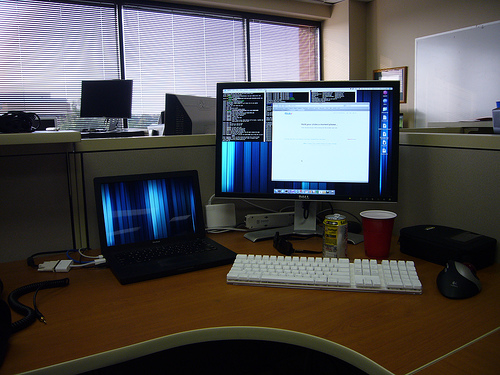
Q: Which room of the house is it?
A: It is an office.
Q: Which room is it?
A: It is an office.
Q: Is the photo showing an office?
A: Yes, it is showing an office.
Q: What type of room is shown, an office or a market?
A: It is an office.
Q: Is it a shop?
A: No, it is an office.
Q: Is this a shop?
A: No, it is an office.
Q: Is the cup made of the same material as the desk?
A: No, the cup is made of plastic and the desk is made of wood.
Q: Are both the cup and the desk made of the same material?
A: No, the cup is made of plastic and the desk is made of wood.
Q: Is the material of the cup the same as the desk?
A: No, the cup is made of plastic and the desk is made of wood.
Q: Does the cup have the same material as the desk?
A: No, the cup is made of plastic and the desk is made of wood.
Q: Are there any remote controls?
A: No, there are no remote controls.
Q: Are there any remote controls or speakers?
A: No, there are no remote controls or speakers.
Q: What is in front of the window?
A: The screen is in front of the window.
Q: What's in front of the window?
A: The screen is in front of the window.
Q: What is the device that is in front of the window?
A: The device is a screen.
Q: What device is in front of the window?
A: The device is a screen.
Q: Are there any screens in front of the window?
A: Yes, there is a screen in front of the window.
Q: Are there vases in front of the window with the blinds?
A: No, there is a screen in front of the window.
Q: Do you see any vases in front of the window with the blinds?
A: No, there is a screen in front of the window.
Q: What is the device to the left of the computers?
A: The device is a screen.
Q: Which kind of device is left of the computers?
A: The device is a screen.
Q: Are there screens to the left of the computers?
A: Yes, there is a screen to the left of the computers.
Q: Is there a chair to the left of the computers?
A: No, there is a screen to the left of the computers.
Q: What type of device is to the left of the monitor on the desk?
A: The device is a screen.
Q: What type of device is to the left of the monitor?
A: The device is a screen.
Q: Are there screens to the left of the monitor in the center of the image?
A: Yes, there is a screen to the left of the monitor.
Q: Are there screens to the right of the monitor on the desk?
A: No, the screen is to the left of the monitor.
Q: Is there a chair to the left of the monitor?
A: No, there is a screen to the left of the monitor.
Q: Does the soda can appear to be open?
A: Yes, the soda can is open.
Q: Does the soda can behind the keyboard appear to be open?
A: Yes, the soda can is open.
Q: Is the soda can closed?
A: No, the soda can is open.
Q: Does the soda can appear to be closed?
A: No, the soda can is open.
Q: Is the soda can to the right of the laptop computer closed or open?
A: The soda can is open.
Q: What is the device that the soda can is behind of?
A: The device is a keyboard.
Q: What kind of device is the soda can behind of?
A: The soda can is behind the keyboard.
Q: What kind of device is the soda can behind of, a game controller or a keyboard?
A: The soda can is behind a keyboard.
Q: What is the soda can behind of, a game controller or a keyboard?
A: The soda can is behind a keyboard.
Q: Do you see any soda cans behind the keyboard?
A: Yes, there is a soda can behind the keyboard.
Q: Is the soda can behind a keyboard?
A: Yes, the soda can is behind a keyboard.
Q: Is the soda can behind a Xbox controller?
A: No, the soda can is behind a keyboard.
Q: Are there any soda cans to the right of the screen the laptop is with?
A: Yes, there is a soda can to the right of the screen.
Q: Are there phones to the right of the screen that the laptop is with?
A: No, there is a soda can to the right of the screen.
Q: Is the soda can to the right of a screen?
A: Yes, the soda can is to the right of a screen.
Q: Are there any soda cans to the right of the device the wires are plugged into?
A: Yes, there is a soda can to the right of the laptop computer.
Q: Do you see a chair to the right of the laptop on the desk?
A: No, there is a soda can to the right of the laptop.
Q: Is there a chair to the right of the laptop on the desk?
A: No, there is a soda can to the right of the laptop.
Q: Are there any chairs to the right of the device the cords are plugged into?
A: No, there is a soda can to the right of the laptop.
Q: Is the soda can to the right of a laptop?
A: Yes, the soda can is to the right of a laptop.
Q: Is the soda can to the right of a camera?
A: No, the soda can is to the right of a laptop.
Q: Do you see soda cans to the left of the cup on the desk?
A: Yes, there is a soda can to the left of the cup.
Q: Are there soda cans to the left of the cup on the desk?
A: Yes, there is a soda can to the left of the cup.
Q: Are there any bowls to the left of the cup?
A: No, there is a soda can to the left of the cup.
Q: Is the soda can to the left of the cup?
A: Yes, the soda can is to the left of the cup.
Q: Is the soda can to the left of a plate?
A: No, the soda can is to the left of the cup.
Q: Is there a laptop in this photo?
A: Yes, there is a laptop.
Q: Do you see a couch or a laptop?
A: Yes, there is a laptop.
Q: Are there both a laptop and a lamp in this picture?
A: No, there is a laptop but no lamps.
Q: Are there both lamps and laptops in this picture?
A: No, there is a laptop but no lamps.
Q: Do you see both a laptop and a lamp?
A: No, there is a laptop but no lamps.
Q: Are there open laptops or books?
A: Yes, there is an open laptop.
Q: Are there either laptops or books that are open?
A: Yes, the laptop is open.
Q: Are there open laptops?
A: Yes, there is an open laptop.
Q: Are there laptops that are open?
A: Yes, there is an open laptop.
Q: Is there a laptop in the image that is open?
A: Yes, there is a laptop that is open.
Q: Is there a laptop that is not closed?
A: Yes, there is a open laptop.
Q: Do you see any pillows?
A: No, there are no pillows.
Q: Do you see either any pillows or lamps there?
A: No, there are no pillows or lamps.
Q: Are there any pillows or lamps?
A: No, there are no pillows or lamps.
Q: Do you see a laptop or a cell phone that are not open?
A: No, there is a laptop but it is open.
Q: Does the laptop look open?
A: Yes, the laptop is open.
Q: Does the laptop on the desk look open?
A: Yes, the laptop is open.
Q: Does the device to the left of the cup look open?
A: Yes, the laptop is open.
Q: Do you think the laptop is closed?
A: No, the laptop is open.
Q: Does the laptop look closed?
A: No, the laptop is open.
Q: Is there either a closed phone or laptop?
A: No, there is a laptop but it is open.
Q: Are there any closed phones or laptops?
A: No, there is a laptop but it is open.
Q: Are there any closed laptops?
A: No, there is a laptop but it is open.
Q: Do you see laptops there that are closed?
A: No, there is a laptop but it is open.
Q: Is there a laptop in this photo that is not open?
A: No, there is a laptop but it is open.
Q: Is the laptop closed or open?
A: The laptop is open.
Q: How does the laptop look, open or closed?
A: The laptop is open.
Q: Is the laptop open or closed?
A: The laptop is open.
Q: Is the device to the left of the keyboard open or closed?
A: The laptop is open.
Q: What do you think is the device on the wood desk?
A: The device is a laptop.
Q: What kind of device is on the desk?
A: The device is a laptop.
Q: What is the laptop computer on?
A: The laptop computer is on the desk.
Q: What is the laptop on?
A: The laptop computer is on the desk.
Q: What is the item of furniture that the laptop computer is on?
A: The piece of furniture is a desk.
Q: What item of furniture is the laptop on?
A: The laptop computer is on the desk.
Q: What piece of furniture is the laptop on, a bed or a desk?
A: The laptop is on a desk.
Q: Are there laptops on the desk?
A: Yes, there is a laptop on the desk.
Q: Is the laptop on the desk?
A: Yes, the laptop is on the desk.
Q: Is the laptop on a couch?
A: No, the laptop is on the desk.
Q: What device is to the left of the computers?
A: The device is a laptop.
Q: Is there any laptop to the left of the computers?
A: Yes, there is a laptop to the left of the computers.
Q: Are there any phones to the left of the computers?
A: No, there is a laptop to the left of the computers.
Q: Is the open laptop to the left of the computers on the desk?
A: Yes, the laptop is to the left of the computers.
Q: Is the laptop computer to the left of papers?
A: No, the laptop computer is to the left of the computers.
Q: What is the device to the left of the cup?
A: The device is a laptop.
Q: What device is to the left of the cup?
A: The device is a laptop.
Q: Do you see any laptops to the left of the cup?
A: Yes, there is a laptop to the left of the cup.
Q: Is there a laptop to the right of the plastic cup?
A: No, the laptop is to the left of the cup.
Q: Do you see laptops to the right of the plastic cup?
A: No, the laptop is to the left of the cup.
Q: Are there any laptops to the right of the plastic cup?
A: No, the laptop is to the left of the cup.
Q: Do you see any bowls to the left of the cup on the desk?
A: No, there is a laptop to the left of the cup.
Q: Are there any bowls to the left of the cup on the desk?
A: No, there is a laptop to the left of the cup.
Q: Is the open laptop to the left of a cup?
A: Yes, the laptop is to the left of a cup.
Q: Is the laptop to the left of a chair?
A: No, the laptop is to the left of a cup.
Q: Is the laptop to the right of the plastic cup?
A: No, the laptop is to the left of the cup.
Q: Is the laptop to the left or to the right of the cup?
A: The laptop is to the left of the cup.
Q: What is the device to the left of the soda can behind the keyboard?
A: The device is a laptop.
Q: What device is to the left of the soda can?
A: The device is a laptop.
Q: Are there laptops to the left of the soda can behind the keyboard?
A: Yes, there is a laptop to the left of the soda can.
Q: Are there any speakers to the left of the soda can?
A: No, there is a laptop to the left of the soda can.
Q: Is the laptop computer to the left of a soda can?
A: Yes, the laptop computer is to the left of a soda can.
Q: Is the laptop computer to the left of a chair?
A: No, the laptop computer is to the left of a soda can.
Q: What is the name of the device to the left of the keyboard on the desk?
A: The device is a laptop.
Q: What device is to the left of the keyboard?
A: The device is a laptop.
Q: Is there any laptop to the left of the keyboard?
A: Yes, there is a laptop to the left of the keyboard.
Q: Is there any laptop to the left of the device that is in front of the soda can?
A: Yes, there is a laptop to the left of the keyboard.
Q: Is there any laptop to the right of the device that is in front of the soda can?
A: No, the laptop is to the left of the keyboard.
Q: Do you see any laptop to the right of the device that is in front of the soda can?
A: No, the laptop is to the left of the keyboard.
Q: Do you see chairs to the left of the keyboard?
A: No, there is a laptop to the left of the keyboard.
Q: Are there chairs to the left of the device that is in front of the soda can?
A: No, there is a laptop to the left of the keyboard.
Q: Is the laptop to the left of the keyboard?
A: Yes, the laptop is to the left of the keyboard.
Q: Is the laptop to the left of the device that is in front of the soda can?
A: Yes, the laptop is to the left of the keyboard.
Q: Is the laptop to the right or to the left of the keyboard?
A: The laptop is to the left of the keyboard.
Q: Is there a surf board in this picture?
A: No, there are no surfboards.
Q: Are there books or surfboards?
A: No, there are no surfboards or books.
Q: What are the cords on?
A: The cords are on the desk.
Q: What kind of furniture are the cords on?
A: The cords are on the desk.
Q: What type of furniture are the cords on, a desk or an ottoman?
A: The cords are on a desk.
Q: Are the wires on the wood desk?
A: Yes, the wires are on the desk.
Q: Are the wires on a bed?
A: No, the wires are on the desk.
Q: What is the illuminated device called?
A: The device is a screen.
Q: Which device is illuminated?
A: The device is a screen.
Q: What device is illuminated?
A: The device is a screen.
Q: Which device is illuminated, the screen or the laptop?
A: The screen is illuminated.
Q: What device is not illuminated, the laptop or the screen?
A: The laptop is not illuminated.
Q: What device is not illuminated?
A: The device is a laptop.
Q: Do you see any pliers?
A: No, there are no pliers.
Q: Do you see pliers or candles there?
A: No, there are no pliers or candles.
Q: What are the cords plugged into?
A: The cords are plugged into the laptop.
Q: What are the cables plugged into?
A: The cords are plugged into the laptop.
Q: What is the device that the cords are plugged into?
A: The device is a laptop.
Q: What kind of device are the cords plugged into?
A: The cords are plugged into the laptop.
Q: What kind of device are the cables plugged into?
A: The cords are plugged into the laptop.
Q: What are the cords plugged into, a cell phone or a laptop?
A: The cords are plugged into a laptop.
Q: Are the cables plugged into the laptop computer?
A: Yes, the cables are plugged into the laptop computer.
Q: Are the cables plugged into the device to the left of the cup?
A: Yes, the cables are plugged into the laptop computer.